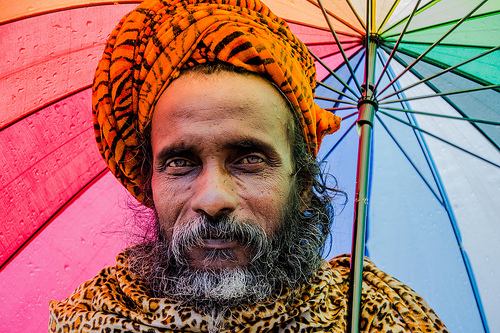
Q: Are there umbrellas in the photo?
A: Yes, there is an umbrella.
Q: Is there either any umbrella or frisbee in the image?
A: Yes, there is an umbrella.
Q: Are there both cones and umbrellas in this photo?
A: No, there is an umbrella but no cones.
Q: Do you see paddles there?
A: No, there are no paddles.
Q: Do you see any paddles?
A: No, there are no paddles.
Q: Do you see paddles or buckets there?
A: No, there are no paddles or buckets.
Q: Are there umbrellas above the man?
A: Yes, there is an umbrella above the man.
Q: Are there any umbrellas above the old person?
A: Yes, there is an umbrella above the man.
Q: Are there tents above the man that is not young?
A: No, there is an umbrella above the man.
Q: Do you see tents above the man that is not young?
A: No, there is an umbrella above the man.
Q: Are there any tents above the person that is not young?
A: No, there is an umbrella above the man.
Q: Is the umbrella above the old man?
A: Yes, the umbrella is above the man.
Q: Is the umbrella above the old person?
A: Yes, the umbrella is above the man.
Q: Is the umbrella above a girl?
A: No, the umbrella is above the man.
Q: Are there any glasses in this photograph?
A: No, there are no glasses.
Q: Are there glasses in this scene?
A: No, there are no glasses.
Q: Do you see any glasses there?
A: No, there are no glasses.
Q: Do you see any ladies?
A: No, there are no ladies.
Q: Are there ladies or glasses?
A: No, there are no ladies or glasses.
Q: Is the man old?
A: Yes, the man is old.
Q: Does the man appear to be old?
A: Yes, the man is old.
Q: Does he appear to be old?
A: Yes, the man is old.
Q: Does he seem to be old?
A: Yes, the man is old.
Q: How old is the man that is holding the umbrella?
A: The man is old.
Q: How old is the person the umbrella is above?
A: The man is old.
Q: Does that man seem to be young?
A: No, the man is old.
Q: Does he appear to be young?
A: No, the man is old.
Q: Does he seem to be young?
A: No, the man is old.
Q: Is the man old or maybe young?
A: The man is old.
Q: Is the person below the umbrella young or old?
A: The man is old.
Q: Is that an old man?
A: Yes, that is an old man.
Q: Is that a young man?
A: No, that is an old man.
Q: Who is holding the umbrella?
A: The man is holding the umbrella.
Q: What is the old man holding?
A: The man is holding the umbrella.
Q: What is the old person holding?
A: The man is holding the umbrella.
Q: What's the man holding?
A: The man is holding the umbrella.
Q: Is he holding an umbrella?
A: Yes, the man is holding an umbrella.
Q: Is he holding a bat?
A: No, the man is holding an umbrella.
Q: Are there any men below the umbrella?
A: Yes, there is a man below the umbrella.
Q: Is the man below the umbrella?
A: Yes, the man is below the umbrella.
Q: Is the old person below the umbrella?
A: Yes, the man is below the umbrella.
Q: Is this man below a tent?
A: No, the man is below the umbrella.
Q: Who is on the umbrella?
A: The man is on the umbrella.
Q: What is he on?
A: The man is on the umbrella.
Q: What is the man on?
A: The man is on the umbrella.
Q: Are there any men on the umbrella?
A: Yes, there is a man on the umbrella.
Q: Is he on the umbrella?
A: Yes, the man is on the umbrella.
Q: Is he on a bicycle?
A: No, the man is on the umbrella.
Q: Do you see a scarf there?
A: Yes, there is a scarf.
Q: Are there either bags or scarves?
A: Yes, there is a scarf.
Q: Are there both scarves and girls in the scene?
A: No, there is a scarf but no girls.